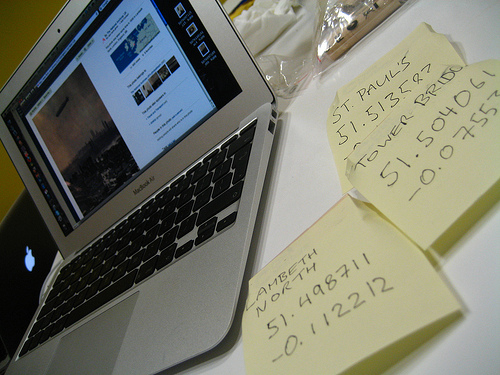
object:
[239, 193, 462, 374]
post it note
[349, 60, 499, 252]
post it note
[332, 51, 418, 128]
writing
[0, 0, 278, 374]
laptop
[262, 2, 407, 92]
plastic wrapper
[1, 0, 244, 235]
screen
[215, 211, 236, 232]
key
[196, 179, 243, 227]
key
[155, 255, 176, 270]
key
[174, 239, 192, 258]
key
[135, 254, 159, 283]
key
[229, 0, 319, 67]
napkin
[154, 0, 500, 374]
table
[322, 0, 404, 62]
object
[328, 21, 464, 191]
post it note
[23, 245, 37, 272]
mac logo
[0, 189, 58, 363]
laptop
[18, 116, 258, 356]
keyboard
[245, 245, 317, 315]
word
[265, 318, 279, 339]
number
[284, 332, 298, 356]
number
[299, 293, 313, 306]
number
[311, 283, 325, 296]
number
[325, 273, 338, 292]
number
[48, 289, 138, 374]
mouse pad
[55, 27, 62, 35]
camera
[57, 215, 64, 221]
icon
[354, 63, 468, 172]
tower bridge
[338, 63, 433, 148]
51513587